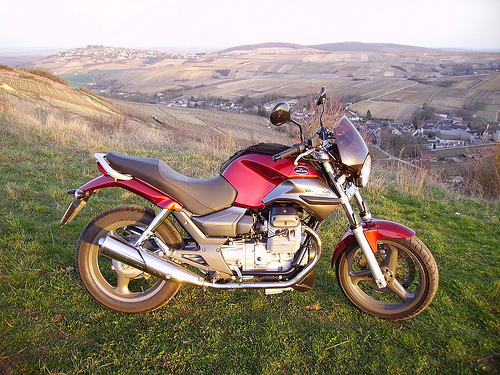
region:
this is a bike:
[61, 118, 464, 348]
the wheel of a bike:
[326, 212, 436, 337]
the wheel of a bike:
[73, 195, 185, 329]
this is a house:
[418, 120, 462, 175]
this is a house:
[217, 84, 239, 119]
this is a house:
[424, 126, 451, 164]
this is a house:
[428, 107, 470, 141]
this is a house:
[353, 94, 388, 143]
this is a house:
[433, 152, 470, 204]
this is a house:
[195, 82, 240, 134]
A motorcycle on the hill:
[75, 108, 480, 348]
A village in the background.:
[68, 38, 164, 95]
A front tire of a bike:
[338, 219, 437, 321]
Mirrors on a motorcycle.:
[267, 100, 298, 133]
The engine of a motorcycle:
[217, 201, 317, 289]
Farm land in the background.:
[264, 40, 425, 135]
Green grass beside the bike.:
[60, 305, 374, 370]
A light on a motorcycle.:
[360, 149, 376, 192]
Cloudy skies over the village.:
[147, 10, 234, 36]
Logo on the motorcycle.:
[290, 167, 315, 176]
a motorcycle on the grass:
[65, 79, 440, 326]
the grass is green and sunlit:
[11, 145, 498, 373]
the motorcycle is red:
[65, 121, 426, 316]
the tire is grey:
[335, 232, 444, 323]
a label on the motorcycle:
[286, 159, 308, 176]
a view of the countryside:
[64, 36, 491, 205]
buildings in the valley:
[372, 92, 491, 155]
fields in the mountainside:
[224, 59, 490, 126]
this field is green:
[61, 65, 112, 87]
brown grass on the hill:
[14, 102, 249, 164]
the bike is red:
[43, 88, 443, 335]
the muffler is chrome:
[97, 221, 204, 292]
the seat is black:
[107, 145, 237, 214]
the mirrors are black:
[265, 85, 336, 129]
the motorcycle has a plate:
[52, 188, 89, 230]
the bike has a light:
[354, 140, 374, 190]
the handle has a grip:
[264, 142, 299, 165]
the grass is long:
[64, 103, 206, 150]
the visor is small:
[335, 111, 362, 162]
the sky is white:
[139, 9, 271, 32]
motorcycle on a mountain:
[59, 93, 455, 343]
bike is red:
[73, 101, 422, 333]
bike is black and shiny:
[45, 86, 451, 357]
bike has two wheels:
[66, 100, 441, 335]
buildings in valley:
[369, 90, 481, 175]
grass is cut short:
[25, 160, 128, 354]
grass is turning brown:
[40, 70, 192, 142]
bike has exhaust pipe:
[84, 226, 227, 307]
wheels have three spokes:
[340, 227, 452, 338]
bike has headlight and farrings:
[351, 145, 396, 202]